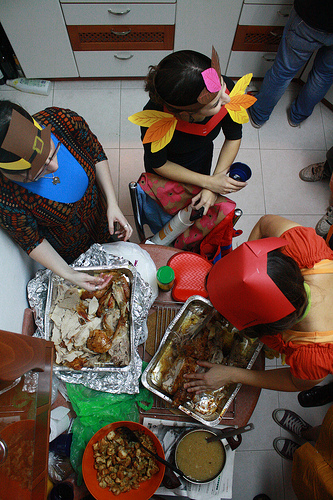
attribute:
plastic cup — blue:
[228, 161, 252, 185]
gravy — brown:
[175, 431, 223, 479]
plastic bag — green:
[70, 382, 143, 422]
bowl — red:
[85, 429, 163, 498]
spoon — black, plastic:
[118, 426, 187, 477]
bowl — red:
[80, 422, 164, 498]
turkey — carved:
[55, 288, 130, 362]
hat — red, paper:
[203, 235, 293, 324]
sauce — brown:
[189, 440, 216, 469]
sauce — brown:
[180, 438, 219, 473]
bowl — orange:
[80, 417, 168, 492]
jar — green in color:
[154, 262, 175, 293]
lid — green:
[156, 265, 174, 281]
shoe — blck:
[271, 402, 309, 440]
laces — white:
[283, 414, 301, 429]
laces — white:
[286, 446, 298, 453]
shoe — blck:
[271, 434, 298, 458]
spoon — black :
[114, 425, 183, 477]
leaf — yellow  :
[127, 109, 174, 127]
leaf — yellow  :
[230, 73, 253, 100]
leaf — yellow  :
[226, 104, 249, 124]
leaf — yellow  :
[150, 118, 177, 153]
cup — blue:
[214, 158, 263, 176]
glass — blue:
[220, 149, 261, 197]